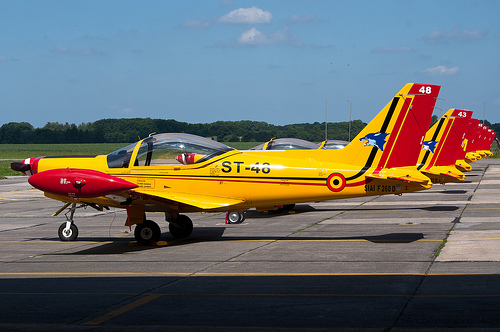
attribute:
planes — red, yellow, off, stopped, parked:
[23, 81, 499, 235]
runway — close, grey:
[2, 151, 500, 330]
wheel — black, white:
[55, 222, 79, 242]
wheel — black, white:
[130, 216, 160, 246]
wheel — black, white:
[163, 215, 194, 235]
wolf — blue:
[357, 130, 392, 155]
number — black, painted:
[252, 158, 271, 176]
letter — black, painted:
[214, 159, 234, 174]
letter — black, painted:
[229, 159, 247, 175]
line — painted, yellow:
[68, 288, 167, 330]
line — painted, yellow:
[3, 264, 423, 279]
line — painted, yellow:
[6, 236, 367, 245]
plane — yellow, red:
[7, 79, 439, 249]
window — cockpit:
[105, 127, 237, 171]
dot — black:
[333, 179, 339, 185]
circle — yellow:
[330, 176, 340, 187]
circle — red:
[320, 172, 348, 192]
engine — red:
[21, 169, 136, 201]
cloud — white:
[219, 2, 273, 25]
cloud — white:
[231, 28, 265, 48]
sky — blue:
[2, 0, 499, 124]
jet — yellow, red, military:
[19, 81, 442, 244]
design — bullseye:
[324, 169, 347, 193]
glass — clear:
[107, 129, 232, 165]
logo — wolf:
[176, 149, 293, 199]